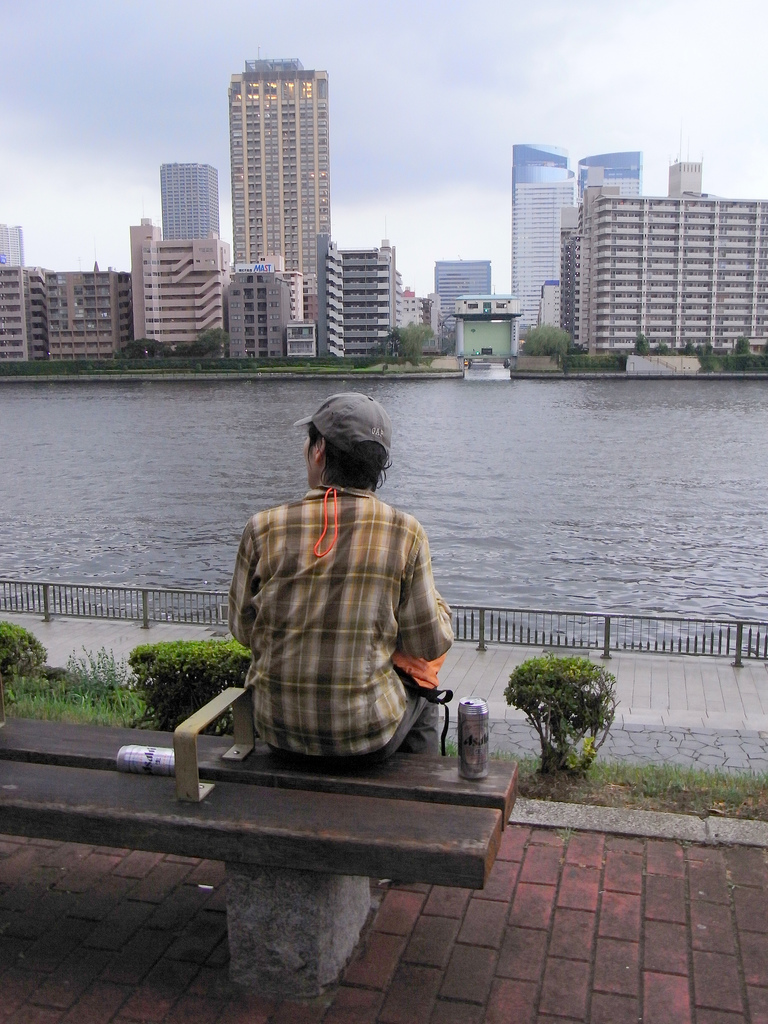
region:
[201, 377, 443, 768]
man sitting on bench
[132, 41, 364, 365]
tall building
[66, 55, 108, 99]
white clouds in blue sky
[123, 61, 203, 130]
white clouds in blue sky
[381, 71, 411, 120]
white clouds in blue sky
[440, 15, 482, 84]
white clouds in blue sky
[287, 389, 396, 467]
Cap on a man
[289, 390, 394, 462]
Grey cap on a man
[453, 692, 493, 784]
Can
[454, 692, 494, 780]
Silver can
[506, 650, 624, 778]
Bush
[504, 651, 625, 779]
Green bush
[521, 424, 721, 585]
Large body of water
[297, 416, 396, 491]
Hair on a man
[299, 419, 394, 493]
Black hair on a man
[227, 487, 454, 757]
Shirt on a man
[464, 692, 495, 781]
can with drink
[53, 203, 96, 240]
white clouds in the blue sky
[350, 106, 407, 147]
white clouds in the blue sky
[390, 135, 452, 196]
white clouds in the blue sky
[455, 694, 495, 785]
a can of drink is on the bench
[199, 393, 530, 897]
a man sits on the bench facing the body of water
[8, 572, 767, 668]
a long side railing or guard near the water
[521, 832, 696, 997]
bricks laid as a pavement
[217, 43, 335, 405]
a tall skyscraper near the body of water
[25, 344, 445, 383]
a long plant hedge along the side of the buildings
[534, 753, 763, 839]
some grass on the patch of ground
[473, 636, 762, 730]
a concrete pathway near the metal sidings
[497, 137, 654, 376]
two similar towers facing each other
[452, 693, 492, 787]
silver can on the bench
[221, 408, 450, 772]
man sitting on the bench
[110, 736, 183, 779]
can laying on the bench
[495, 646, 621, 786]
tree in front of the bench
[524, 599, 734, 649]
railing on the sidewalk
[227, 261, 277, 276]
sign on top of the skyscraper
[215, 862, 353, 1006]
cement block at the bottom of the bench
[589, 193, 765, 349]
skyscraper across the water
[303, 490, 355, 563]
orange string on the shirt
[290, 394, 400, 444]
gray cap on the head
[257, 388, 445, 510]
head of the person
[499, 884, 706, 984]
lines on the ground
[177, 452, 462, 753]
back of the person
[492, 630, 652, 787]
bush in front of person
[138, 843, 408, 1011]
gray part of bench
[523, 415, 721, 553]
water in front of man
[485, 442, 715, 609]
waves in front of the person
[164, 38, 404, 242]
building near the water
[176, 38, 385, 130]
top of the building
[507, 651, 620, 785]
small bush near a wooden bench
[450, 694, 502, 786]
A beverage can on a bench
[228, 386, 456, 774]
A man sitting on a wooden bench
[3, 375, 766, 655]
A body of water in front of the buildings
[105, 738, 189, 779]
A can lying on its side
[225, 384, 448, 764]
Person in a grey cap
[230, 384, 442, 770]
A person in a brown plaid shirt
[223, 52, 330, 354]
The tallest sky scraper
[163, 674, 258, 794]
A metal bar on a wooden bench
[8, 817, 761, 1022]
walkway of red brick pavers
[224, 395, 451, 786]
man sitting on a bench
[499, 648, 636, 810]
small green bush